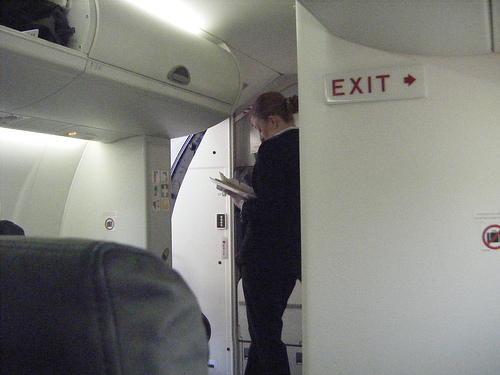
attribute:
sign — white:
[311, 65, 441, 119]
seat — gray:
[13, 229, 241, 370]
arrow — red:
[396, 66, 423, 95]